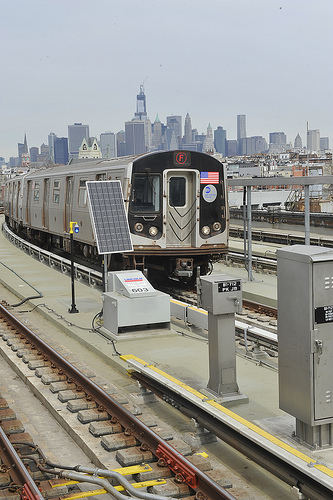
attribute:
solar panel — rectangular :
[87, 175, 142, 324]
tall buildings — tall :
[2, 80, 331, 161]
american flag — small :
[197, 170, 220, 182]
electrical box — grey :
[275, 239, 328, 447]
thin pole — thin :
[66, 218, 82, 322]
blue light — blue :
[72, 222, 85, 237]